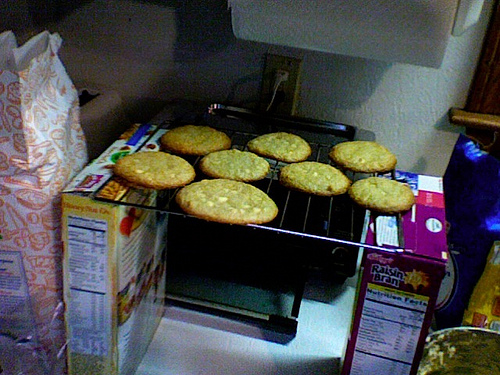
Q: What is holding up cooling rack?
A: Two boxes of cereals.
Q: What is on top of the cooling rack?
A: Cookies.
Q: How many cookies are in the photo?
A: Eight.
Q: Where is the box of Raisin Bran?
A: Under the right side of the cooling rack.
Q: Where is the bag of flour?
A: On the far left next to the cereal box.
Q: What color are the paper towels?
A: White.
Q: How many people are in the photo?
A: None.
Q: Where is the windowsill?
A: Just above the bright blue bag.